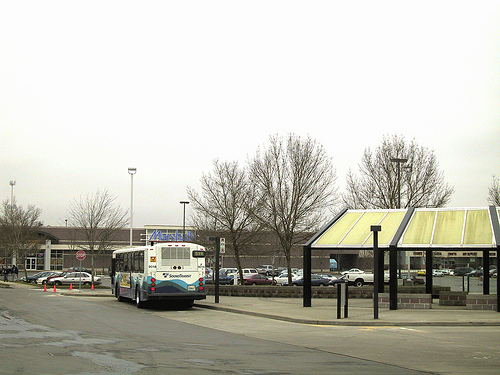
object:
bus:
[109, 239, 208, 310]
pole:
[368, 224, 382, 320]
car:
[47, 271, 104, 286]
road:
[0, 283, 500, 375]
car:
[345, 269, 399, 288]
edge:
[193, 302, 499, 327]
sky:
[0, 0, 500, 229]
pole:
[127, 165, 138, 247]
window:
[160, 246, 190, 259]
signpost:
[75, 249, 88, 292]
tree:
[185, 157, 280, 287]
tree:
[232, 130, 343, 287]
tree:
[327, 132, 457, 279]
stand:
[302, 245, 311, 307]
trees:
[54, 186, 131, 290]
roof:
[302, 204, 500, 251]